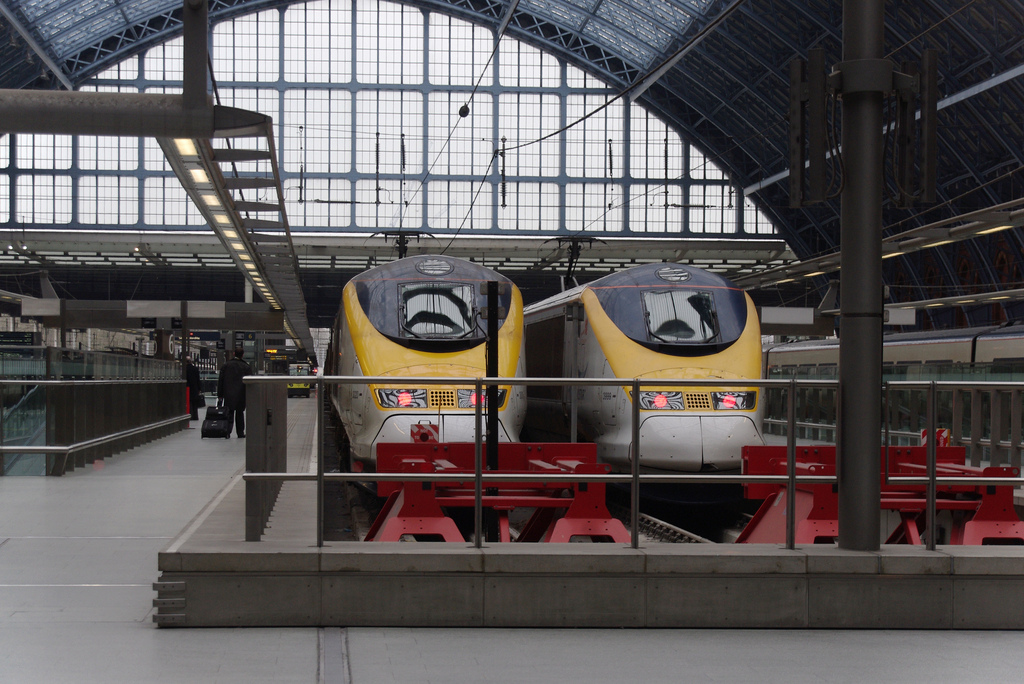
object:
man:
[217, 348, 252, 438]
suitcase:
[201, 399, 236, 440]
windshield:
[350, 254, 514, 353]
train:
[323, 254, 526, 501]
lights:
[173, 138, 283, 310]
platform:
[0, 390, 1024, 684]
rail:
[239, 375, 1024, 550]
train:
[521, 263, 764, 504]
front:
[340, 254, 524, 459]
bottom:
[629, 415, 769, 473]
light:
[629, 391, 686, 410]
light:
[710, 391, 756, 410]